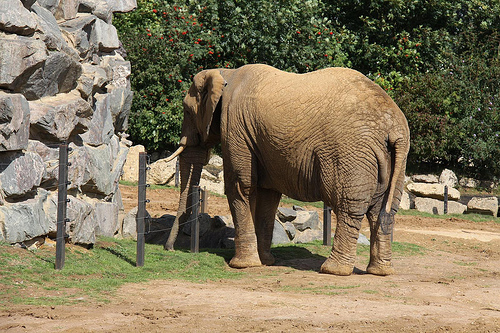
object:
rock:
[1, 0, 496, 249]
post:
[55, 146, 200, 271]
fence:
[55, 140, 330, 270]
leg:
[226, 139, 410, 277]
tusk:
[164, 145, 187, 162]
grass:
[0, 234, 426, 309]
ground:
[0, 180, 500, 333]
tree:
[112, 0, 500, 180]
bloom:
[111, 0, 227, 57]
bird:
[120, 70, 129, 85]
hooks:
[55, 145, 201, 270]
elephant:
[162, 64, 410, 276]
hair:
[378, 208, 391, 232]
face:
[183, 69, 224, 142]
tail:
[385, 133, 409, 215]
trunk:
[164, 144, 210, 251]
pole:
[136, 152, 146, 264]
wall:
[0, 0, 137, 251]